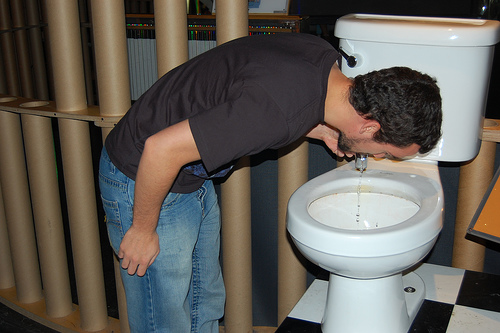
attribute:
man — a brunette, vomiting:
[92, 30, 444, 332]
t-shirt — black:
[103, 31, 342, 194]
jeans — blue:
[97, 142, 232, 331]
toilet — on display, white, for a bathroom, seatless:
[284, 10, 497, 331]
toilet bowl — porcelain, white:
[282, 162, 446, 258]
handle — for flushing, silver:
[335, 43, 360, 69]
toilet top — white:
[333, 10, 499, 49]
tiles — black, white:
[277, 260, 498, 332]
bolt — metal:
[403, 283, 417, 297]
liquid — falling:
[346, 150, 374, 231]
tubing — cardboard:
[1, 0, 307, 332]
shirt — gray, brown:
[105, 31, 344, 194]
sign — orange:
[465, 164, 500, 248]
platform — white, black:
[273, 254, 500, 330]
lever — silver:
[334, 40, 361, 71]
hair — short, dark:
[348, 62, 444, 153]